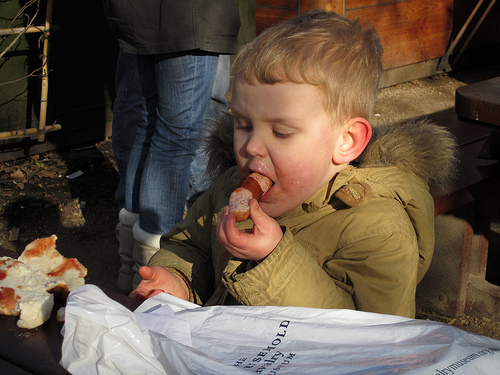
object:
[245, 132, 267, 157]
nose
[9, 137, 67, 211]
dirt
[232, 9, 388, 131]
hair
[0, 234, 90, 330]
bread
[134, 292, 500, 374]
bag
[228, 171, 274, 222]
hotdog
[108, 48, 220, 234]
blue jeans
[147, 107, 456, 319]
jacket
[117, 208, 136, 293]
boots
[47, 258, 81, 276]
ketchup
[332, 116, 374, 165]
ear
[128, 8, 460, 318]
baby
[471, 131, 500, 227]
bench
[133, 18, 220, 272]
legs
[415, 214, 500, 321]
wooden chair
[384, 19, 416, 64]
board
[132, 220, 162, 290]
boots